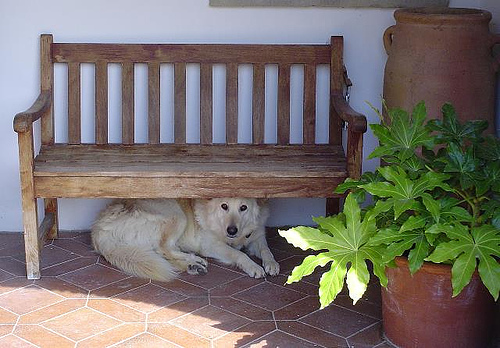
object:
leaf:
[406, 233, 431, 279]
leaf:
[450, 244, 477, 298]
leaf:
[376, 162, 408, 198]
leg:
[198, 233, 270, 279]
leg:
[248, 234, 282, 277]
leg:
[151, 205, 209, 268]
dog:
[86, 198, 283, 284]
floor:
[0, 226, 389, 348]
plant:
[271, 98, 500, 314]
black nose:
[225, 222, 240, 236]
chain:
[341, 69, 354, 130]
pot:
[381, 7, 500, 167]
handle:
[382, 24, 396, 55]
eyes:
[220, 202, 228, 211]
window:
[207, 0, 403, 10]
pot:
[376, 245, 494, 346]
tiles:
[171, 303, 249, 341]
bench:
[13, 34, 367, 279]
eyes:
[240, 204, 248, 211]